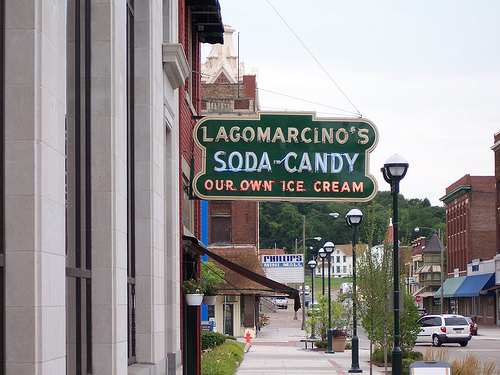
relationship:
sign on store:
[193, 109, 382, 205] [179, 1, 203, 372]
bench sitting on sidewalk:
[300, 335, 322, 352] [231, 306, 393, 373]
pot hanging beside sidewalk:
[179, 277, 206, 310] [231, 306, 393, 373]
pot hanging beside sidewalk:
[184, 292, 217, 306] [231, 306, 393, 373]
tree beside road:
[304, 201, 423, 373] [299, 293, 498, 372]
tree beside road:
[342, 201, 384, 373] [299, 293, 498, 372]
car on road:
[412, 313, 474, 348] [299, 293, 498, 372]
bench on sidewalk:
[300, 335, 322, 352] [231, 306, 393, 373]